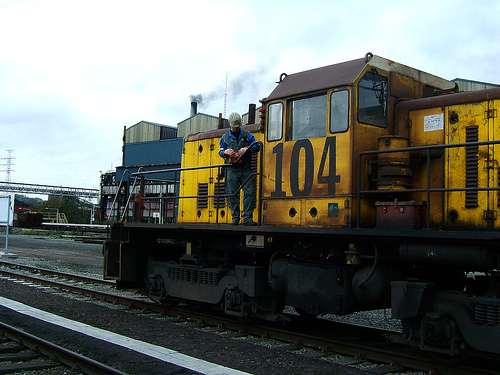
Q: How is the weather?
A: It is cloudy.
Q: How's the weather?
A: It is cloudy.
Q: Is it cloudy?
A: Yes, it is cloudy.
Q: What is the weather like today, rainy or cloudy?
A: It is cloudy.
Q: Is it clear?
A: No, it is cloudy.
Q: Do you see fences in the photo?
A: No, there are no fences.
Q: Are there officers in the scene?
A: No, there are no officers.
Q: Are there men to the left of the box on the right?
A: Yes, there is a man to the left of the box.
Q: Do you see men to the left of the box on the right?
A: Yes, there is a man to the left of the box.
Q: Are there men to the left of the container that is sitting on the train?
A: Yes, there is a man to the left of the box.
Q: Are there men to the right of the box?
A: No, the man is to the left of the box.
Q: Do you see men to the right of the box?
A: No, the man is to the left of the box.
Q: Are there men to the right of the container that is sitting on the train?
A: No, the man is to the left of the box.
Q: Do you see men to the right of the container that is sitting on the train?
A: No, the man is to the left of the box.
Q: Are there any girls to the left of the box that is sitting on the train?
A: No, there is a man to the left of the box.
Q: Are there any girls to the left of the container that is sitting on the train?
A: No, there is a man to the left of the box.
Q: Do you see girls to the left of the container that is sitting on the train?
A: No, there is a man to the left of the box.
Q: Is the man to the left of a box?
A: Yes, the man is to the left of a box.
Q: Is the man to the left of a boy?
A: No, the man is to the left of a box.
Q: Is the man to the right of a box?
A: No, the man is to the left of a box.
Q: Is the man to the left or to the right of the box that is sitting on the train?
A: The man is to the left of the box.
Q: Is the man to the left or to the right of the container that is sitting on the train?
A: The man is to the left of the box.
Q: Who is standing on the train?
A: The man is standing on the train.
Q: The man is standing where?
A: The man is standing on the train.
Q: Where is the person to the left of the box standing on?
A: The man is standing on the train.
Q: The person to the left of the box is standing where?
A: The man is standing on the train.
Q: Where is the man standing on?
A: The man is standing on the train.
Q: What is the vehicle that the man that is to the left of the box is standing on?
A: The vehicle is a train.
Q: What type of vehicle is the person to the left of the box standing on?
A: The man is standing on the train.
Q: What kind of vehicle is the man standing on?
A: The man is standing on the train.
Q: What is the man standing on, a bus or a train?
A: The man is standing on a train.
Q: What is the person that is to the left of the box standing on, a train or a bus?
A: The man is standing on a train.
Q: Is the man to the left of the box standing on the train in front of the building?
A: Yes, the man is standing on the train.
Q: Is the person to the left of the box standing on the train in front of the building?
A: Yes, the man is standing on the train.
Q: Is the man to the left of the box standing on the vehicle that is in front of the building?
A: Yes, the man is standing on the train.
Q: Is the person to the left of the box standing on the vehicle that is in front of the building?
A: Yes, the man is standing on the train.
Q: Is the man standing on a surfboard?
A: No, the man is standing on the train.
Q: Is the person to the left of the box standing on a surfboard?
A: No, the man is standing on the train.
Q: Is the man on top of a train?
A: Yes, the man is on top of a train.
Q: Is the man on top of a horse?
A: No, the man is on top of a train.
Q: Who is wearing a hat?
A: The man is wearing a hat.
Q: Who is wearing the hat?
A: The man is wearing a hat.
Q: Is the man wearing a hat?
A: Yes, the man is wearing a hat.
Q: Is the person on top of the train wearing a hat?
A: Yes, the man is wearing a hat.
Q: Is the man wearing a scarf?
A: No, the man is wearing a hat.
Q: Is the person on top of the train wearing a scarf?
A: No, the man is wearing a hat.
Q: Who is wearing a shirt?
A: The man is wearing a shirt.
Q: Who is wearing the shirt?
A: The man is wearing a shirt.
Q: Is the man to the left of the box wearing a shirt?
A: Yes, the man is wearing a shirt.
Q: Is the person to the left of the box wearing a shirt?
A: Yes, the man is wearing a shirt.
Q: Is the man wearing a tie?
A: No, the man is wearing a shirt.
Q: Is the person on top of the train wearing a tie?
A: No, the man is wearing a shirt.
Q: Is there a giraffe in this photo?
A: No, there are no giraffes.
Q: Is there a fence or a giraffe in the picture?
A: No, there are no giraffes or fences.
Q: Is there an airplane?
A: No, there are no airplanes.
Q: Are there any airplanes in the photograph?
A: No, there are no airplanes.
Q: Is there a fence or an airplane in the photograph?
A: No, there are no airplanes or fences.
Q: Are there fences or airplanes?
A: No, there are no airplanes or fences.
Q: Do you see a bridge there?
A: Yes, there is a bridge.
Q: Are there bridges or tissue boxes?
A: Yes, there is a bridge.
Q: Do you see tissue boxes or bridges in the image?
A: Yes, there is a bridge.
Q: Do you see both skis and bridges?
A: No, there is a bridge but no skis.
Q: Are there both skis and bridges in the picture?
A: No, there is a bridge but no skis.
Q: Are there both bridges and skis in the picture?
A: No, there is a bridge but no skis.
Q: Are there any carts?
A: No, there are no carts.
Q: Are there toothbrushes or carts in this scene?
A: No, there are no carts or toothbrushes.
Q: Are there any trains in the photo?
A: Yes, there is a train.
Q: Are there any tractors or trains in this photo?
A: Yes, there is a train.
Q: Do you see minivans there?
A: No, there are no minivans.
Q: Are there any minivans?
A: No, there are no minivans.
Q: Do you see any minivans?
A: No, there are no minivans.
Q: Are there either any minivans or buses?
A: No, there are no minivans or buses.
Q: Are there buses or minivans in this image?
A: No, there are no minivans or buses.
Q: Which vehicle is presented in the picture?
A: The vehicle is a train.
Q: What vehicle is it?
A: The vehicle is a train.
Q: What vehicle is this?
A: This is a train.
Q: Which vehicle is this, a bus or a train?
A: This is a train.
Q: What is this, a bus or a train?
A: This is a train.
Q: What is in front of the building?
A: The train is in front of the building.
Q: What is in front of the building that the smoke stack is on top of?
A: The train is in front of the building.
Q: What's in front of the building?
A: The train is in front of the building.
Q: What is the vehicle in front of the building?
A: The vehicle is a train.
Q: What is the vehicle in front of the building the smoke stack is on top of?
A: The vehicle is a train.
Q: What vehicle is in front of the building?
A: The vehicle is a train.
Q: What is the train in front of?
A: The train is in front of the building.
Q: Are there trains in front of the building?
A: Yes, there is a train in front of the building.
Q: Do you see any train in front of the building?
A: Yes, there is a train in front of the building.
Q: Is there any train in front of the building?
A: Yes, there is a train in front of the building.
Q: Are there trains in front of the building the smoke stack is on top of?
A: Yes, there is a train in front of the building.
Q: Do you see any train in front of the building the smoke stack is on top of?
A: Yes, there is a train in front of the building.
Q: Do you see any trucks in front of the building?
A: No, there is a train in front of the building.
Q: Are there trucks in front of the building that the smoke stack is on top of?
A: No, there is a train in front of the building.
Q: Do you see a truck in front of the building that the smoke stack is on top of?
A: No, there is a train in front of the building.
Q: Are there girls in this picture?
A: No, there are no girls.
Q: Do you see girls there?
A: No, there are no girls.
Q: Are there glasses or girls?
A: No, there are no girls or glasses.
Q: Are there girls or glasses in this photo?
A: No, there are no girls or glasses.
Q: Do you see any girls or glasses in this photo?
A: No, there are no girls or glasses.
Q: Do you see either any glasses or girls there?
A: No, there are no girls or glasses.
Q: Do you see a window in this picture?
A: Yes, there is a window.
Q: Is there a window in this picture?
A: Yes, there is a window.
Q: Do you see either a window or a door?
A: Yes, there is a window.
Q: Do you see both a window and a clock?
A: No, there is a window but no clocks.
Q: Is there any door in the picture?
A: No, there are no doors.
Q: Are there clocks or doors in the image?
A: No, there are no doors or clocks.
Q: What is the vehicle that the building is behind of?
A: The vehicle is a train.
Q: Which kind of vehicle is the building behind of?
A: The building is behind the train.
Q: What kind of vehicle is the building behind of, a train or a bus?
A: The building is behind a train.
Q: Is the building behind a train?
A: Yes, the building is behind a train.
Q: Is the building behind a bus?
A: No, the building is behind a train.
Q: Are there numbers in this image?
A: Yes, there are numbers.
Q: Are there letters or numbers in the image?
A: Yes, there are numbers.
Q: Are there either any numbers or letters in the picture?
A: Yes, there are numbers.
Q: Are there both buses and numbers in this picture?
A: No, there are numbers but no buses.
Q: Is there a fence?
A: No, there are no fences.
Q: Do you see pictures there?
A: No, there are no pictures.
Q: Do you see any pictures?
A: No, there are no pictures.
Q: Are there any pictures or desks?
A: No, there are no pictures or desks.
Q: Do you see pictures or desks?
A: No, there are no pictures or desks.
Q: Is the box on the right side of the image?
A: Yes, the box is on the right of the image.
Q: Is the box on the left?
A: No, the box is on the right of the image.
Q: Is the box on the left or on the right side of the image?
A: The box is on the right of the image.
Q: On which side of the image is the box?
A: The box is on the right of the image.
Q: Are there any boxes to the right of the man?
A: Yes, there is a box to the right of the man.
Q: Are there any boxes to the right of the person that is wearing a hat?
A: Yes, there is a box to the right of the man.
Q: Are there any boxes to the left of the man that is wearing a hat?
A: No, the box is to the right of the man.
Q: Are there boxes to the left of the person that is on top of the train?
A: No, the box is to the right of the man.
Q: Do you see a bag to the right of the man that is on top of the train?
A: No, there is a box to the right of the man.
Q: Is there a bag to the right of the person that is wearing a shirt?
A: No, there is a box to the right of the man.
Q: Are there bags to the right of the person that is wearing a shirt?
A: No, there is a box to the right of the man.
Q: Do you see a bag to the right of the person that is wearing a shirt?
A: No, there is a box to the right of the man.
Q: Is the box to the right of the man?
A: Yes, the box is to the right of the man.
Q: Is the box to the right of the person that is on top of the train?
A: Yes, the box is to the right of the man.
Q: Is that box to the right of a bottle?
A: No, the box is to the right of the man.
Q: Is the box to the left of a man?
A: No, the box is to the right of a man.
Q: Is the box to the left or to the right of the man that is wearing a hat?
A: The box is to the right of the man.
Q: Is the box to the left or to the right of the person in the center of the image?
A: The box is to the right of the man.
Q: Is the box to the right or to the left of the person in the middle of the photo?
A: The box is to the right of the man.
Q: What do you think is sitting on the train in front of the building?
A: The box is sitting on the train.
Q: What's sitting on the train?
A: The box is sitting on the train.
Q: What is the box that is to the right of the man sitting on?
A: The box is sitting on the train.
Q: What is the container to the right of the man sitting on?
A: The box is sitting on the train.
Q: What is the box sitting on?
A: The box is sitting on the train.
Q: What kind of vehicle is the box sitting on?
A: The box is sitting on the train.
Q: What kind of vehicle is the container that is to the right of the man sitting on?
A: The box is sitting on the train.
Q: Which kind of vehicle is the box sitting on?
A: The box is sitting on the train.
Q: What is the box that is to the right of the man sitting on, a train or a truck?
A: The box is sitting on a train.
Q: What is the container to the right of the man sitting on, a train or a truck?
A: The box is sitting on a train.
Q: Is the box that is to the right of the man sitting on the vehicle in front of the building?
A: Yes, the box is sitting on the train.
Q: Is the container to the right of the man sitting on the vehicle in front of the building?
A: Yes, the box is sitting on the train.